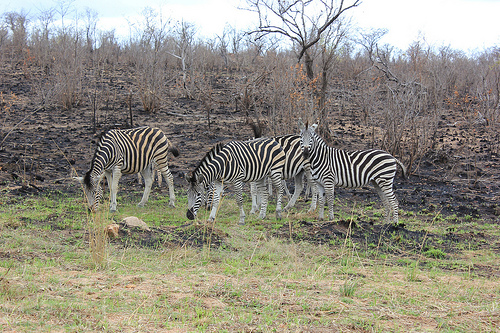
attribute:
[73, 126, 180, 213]
zebra — eating, standing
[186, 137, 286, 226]
zebra — grazing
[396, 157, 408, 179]
tail — black, white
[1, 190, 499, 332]
grass — green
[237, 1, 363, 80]
tree — bare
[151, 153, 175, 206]
leg — white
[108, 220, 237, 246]
dirt — brown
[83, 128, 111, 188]
mane — black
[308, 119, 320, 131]
ear — white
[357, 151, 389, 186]
stripe — black